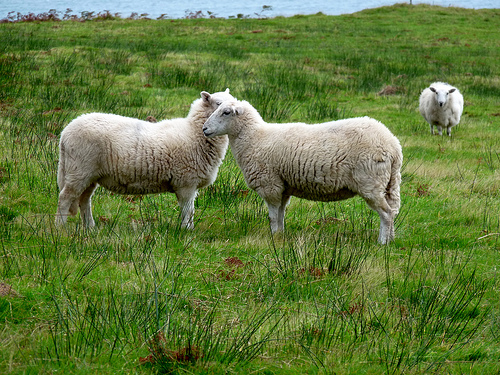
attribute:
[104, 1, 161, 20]
ocean — blue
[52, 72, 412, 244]
sheep — gathered, big, white, together, standing, still, grazing, black, eating, walking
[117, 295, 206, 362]
bushes — red, grassy